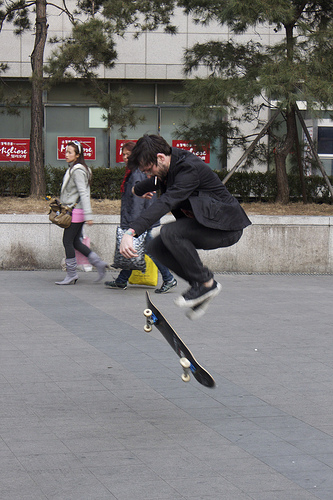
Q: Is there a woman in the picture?
A: Yes, there is a woman.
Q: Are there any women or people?
A: Yes, there is a woman.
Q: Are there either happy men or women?
A: Yes, there is a happy woman.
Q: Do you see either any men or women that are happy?
A: Yes, the woman is happy.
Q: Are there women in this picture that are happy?
A: Yes, there is a happy woman.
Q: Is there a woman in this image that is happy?
A: Yes, there is a woman that is happy.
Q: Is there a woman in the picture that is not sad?
A: Yes, there is a happy woman.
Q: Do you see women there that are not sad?
A: Yes, there is a happy woman.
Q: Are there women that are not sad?
A: Yes, there is a happy woman.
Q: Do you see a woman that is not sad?
A: Yes, there is a happy woman.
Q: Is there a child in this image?
A: No, there are no children.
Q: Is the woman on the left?
A: Yes, the woman is on the left of the image.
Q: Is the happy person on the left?
A: Yes, the woman is on the left of the image.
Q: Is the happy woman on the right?
A: No, the woman is on the left of the image.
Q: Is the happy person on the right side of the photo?
A: No, the woman is on the left of the image.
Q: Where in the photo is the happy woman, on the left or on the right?
A: The woman is on the left of the image.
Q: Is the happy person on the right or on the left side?
A: The woman is on the left of the image.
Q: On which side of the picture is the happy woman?
A: The woman is on the left of the image.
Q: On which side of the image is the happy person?
A: The woman is on the left of the image.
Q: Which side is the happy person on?
A: The woman is on the left of the image.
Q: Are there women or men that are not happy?
A: No, there is a woman but she is happy.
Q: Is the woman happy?
A: Yes, the woman is happy.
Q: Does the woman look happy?
A: Yes, the woman is happy.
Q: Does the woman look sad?
A: No, the woman is happy.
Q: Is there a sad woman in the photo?
A: No, there is a woman but she is happy.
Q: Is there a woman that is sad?
A: No, there is a woman but she is happy.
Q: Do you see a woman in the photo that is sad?
A: No, there is a woman but she is happy.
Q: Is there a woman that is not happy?
A: No, there is a woman but she is happy.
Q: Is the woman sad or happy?
A: The woman is happy.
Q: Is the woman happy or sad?
A: The woman is happy.